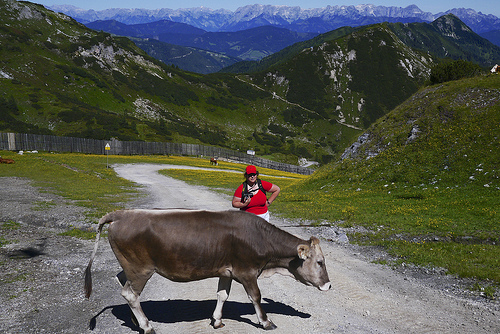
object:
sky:
[38, 0, 497, 10]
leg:
[209, 275, 247, 332]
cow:
[84, 207, 335, 332]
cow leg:
[224, 259, 281, 331]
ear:
[294, 242, 314, 262]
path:
[104, 149, 498, 331]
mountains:
[92, 2, 500, 57]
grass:
[0, 118, 500, 248]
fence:
[1, 127, 326, 183]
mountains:
[0, 0, 334, 149]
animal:
[209, 157, 218, 166]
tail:
[83, 209, 113, 297]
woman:
[231, 163, 281, 225]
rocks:
[72, 267, 81, 271]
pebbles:
[382, 301, 419, 326]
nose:
[325, 282, 332, 291]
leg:
[118, 275, 161, 324]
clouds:
[41, 0, 500, 14]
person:
[224, 157, 279, 224]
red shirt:
[231, 182, 278, 216]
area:
[0, 143, 133, 241]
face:
[296, 235, 339, 290]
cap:
[246, 164, 258, 174]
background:
[0, 0, 500, 156]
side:
[1, 0, 181, 145]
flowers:
[375, 174, 407, 208]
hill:
[279, 79, 499, 284]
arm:
[262, 180, 281, 205]